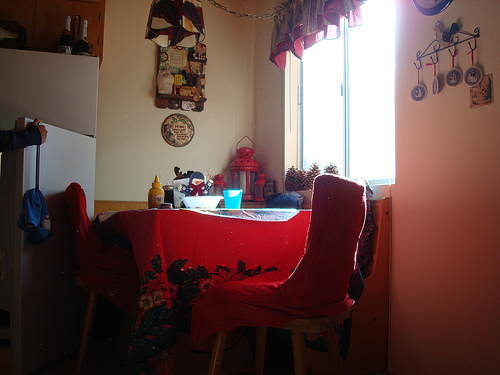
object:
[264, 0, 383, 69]
curtain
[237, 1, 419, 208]
window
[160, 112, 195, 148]
decoration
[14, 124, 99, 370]
refrigerator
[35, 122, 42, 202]
handle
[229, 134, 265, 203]
lantern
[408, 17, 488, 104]
objects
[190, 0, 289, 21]
chain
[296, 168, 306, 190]
cone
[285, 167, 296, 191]
cone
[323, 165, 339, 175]
cone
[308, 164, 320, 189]
cone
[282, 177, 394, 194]
windowsill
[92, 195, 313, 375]
table cloth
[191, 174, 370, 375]
chair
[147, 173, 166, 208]
bottle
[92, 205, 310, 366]
table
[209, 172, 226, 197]
lantern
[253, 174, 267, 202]
lantern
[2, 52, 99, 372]
refrigerator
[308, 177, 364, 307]
cover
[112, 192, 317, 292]
slip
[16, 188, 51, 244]
blue towel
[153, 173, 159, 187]
pointed top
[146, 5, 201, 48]
lamp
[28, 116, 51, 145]
hand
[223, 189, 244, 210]
cup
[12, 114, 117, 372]
fridge door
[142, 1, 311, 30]
ceiling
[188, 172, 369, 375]
kitchen chair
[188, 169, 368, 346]
slip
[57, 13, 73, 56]
bottle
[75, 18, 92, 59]
bottle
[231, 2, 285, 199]
corner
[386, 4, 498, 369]
wall